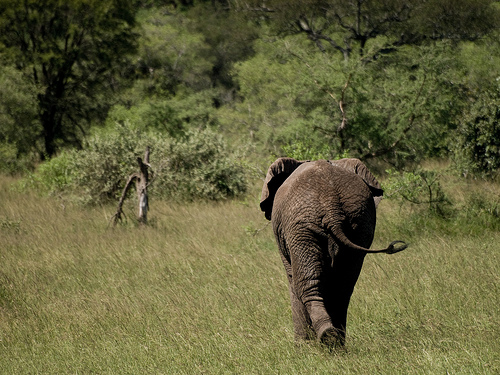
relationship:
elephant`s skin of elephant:
[271, 160, 376, 339] [257, 154, 409, 349]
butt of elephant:
[287, 172, 370, 236] [253, 139, 418, 355]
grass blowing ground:
[399, 200, 490, 312] [39, 279, 204, 369]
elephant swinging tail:
[257, 154, 409, 349] [320, 193, 410, 253]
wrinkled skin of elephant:
[279, 177, 331, 306] [244, 152, 413, 347]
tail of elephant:
[309, 189, 436, 271] [207, 117, 419, 361]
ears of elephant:
[257, 149, 391, 214] [216, 108, 426, 372]